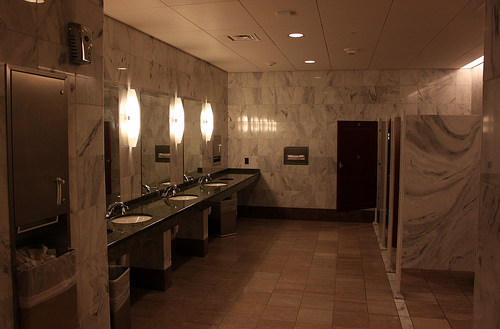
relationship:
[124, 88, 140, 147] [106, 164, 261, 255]
light above wash basins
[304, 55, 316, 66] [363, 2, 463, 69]
light on ceiling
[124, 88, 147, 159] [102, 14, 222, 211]
light on wall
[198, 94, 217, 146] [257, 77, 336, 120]
light on wall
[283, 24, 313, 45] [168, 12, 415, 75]
light on ceiling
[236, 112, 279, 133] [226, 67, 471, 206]
light reflected on marble wall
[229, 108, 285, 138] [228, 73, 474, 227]
relection on wall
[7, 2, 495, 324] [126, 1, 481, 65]
bathroom has ceiling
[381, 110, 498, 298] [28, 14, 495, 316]
bathroom stalls inside bathroom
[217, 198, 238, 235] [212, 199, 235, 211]
trash can lined with plastic bag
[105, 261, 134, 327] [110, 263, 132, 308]
trash can lined with plastic bag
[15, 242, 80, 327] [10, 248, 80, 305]
trash can lined with plastic bag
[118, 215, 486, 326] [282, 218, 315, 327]
floor covered with brown tile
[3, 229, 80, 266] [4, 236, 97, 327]
garbage in trash can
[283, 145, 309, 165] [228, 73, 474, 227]
dispenser mounted on wall